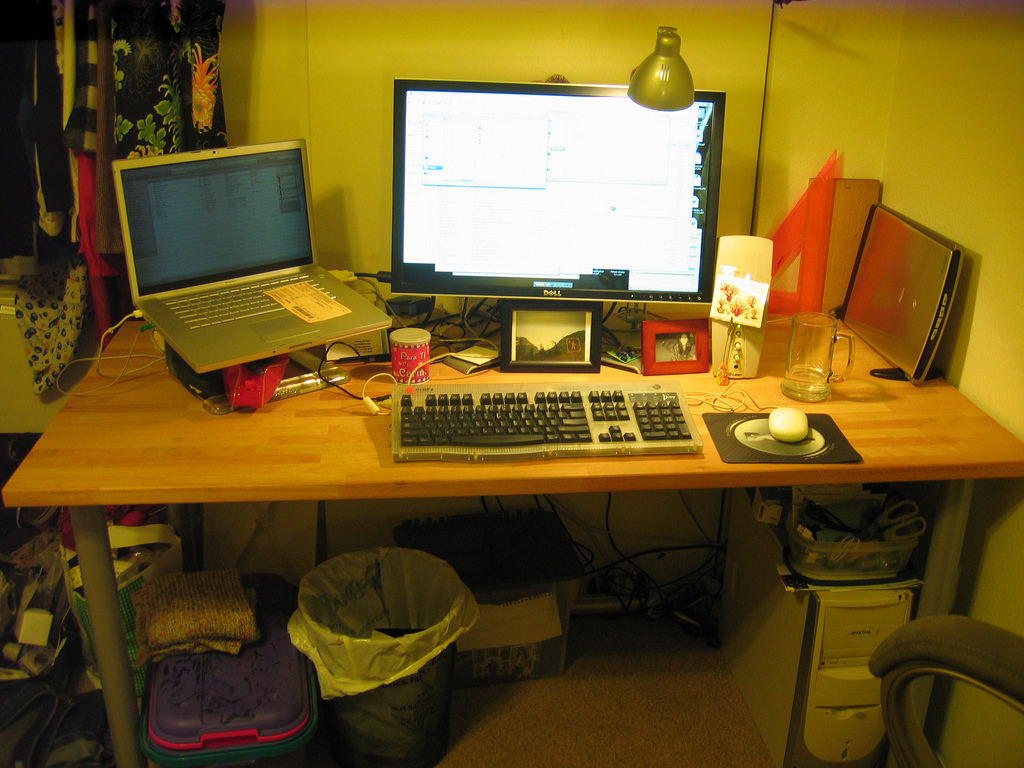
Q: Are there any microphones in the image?
A: No, there are no microphones.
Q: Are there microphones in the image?
A: No, there are no microphones.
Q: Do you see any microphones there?
A: No, there are no microphones.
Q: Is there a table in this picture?
A: Yes, there is a table.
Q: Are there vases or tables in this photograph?
A: Yes, there is a table.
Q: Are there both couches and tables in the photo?
A: No, there is a table but no couches.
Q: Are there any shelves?
A: No, there are no shelves.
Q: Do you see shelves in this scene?
A: No, there are no shelves.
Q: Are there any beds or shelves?
A: No, there are no shelves or beds.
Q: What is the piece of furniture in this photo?
A: The piece of furniture is a table.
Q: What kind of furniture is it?
A: The piece of furniture is a table.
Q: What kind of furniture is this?
A: This is a table.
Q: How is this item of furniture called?
A: This is a table.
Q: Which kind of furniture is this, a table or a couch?
A: This is a table.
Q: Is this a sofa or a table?
A: This is a table.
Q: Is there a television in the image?
A: No, there are no televisions.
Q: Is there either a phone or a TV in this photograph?
A: No, there are no televisions or phones.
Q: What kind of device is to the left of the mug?
A: The devices are computers.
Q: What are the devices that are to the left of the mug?
A: The devices are computers.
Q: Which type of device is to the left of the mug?
A: The devices are computers.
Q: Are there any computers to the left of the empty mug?
A: Yes, there are computers to the left of the mug.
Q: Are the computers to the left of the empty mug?
A: Yes, the computers are to the left of the mug.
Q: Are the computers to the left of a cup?
A: No, the computers are to the left of the mug.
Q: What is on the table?
A: The computers are on the table.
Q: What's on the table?
A: The computers are on the table.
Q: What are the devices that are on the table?
A: The devices are computers.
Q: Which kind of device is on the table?
A: The devices are computers.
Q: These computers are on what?
A: The computers are on the table.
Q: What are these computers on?
A: The computers are on the table.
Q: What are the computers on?
A: The computers are on the table.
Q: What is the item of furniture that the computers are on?
A: The piece of furniture is a table.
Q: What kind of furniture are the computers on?
A: The computers are on the table.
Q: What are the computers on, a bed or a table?
A: The computers are on a table.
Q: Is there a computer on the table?
A: Yes, there are computers on the table.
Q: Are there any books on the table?
A: No, there are computers on the table.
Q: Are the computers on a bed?
A: No, the computers are on the table.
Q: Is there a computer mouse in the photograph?
A: Yes, there is a computer mouse.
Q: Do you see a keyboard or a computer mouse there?
A: Yes, there is a computer mouse.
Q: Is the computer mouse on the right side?
A: Yes, the computer mouse is on the right of the image.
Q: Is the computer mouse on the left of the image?
A: No, the computer mouse is on the right of the image.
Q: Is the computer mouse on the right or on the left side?
A: The computer mouse is on the right of the image.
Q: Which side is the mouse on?
A: The mouse is on the right of the image.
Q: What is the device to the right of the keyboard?
A: The device is a computer mouse.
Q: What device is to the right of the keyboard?
A: The device is a computer mouse.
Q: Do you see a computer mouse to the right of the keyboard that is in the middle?
A: Yes, there is a computer mouse to the right of the keyboard.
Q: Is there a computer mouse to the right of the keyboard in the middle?
A: Yes, there is a computer mouse to the right of the keyboard.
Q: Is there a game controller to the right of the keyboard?
A: No, there is a computer mouse to the right of the keyboard.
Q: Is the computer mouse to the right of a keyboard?
A: Yes, the computer mouse is to the right of a keyboard.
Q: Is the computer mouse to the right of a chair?
A: No, the computer mouse is to the right of a keyboard.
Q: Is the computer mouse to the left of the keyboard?
A: No, the computer mouse is to the right of the keyboard.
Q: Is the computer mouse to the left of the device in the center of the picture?
A: No, the computer mouse is to the right of the keyboard.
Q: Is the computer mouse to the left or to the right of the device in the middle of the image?
A: The computer mouse is to the right of the keyboard.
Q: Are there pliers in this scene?
A: No, there are no pliers.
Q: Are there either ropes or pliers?
A: No, there are no pliers or ropes.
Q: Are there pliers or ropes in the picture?
A: No, there are no pliers or ropes.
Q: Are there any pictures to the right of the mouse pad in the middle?
A: Yes, there is a picture to the right of the mousepad.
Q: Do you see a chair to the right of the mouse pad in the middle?
A: No, there is a picture to the right of the mouse pad.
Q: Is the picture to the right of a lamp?
A: No, the picture is to the right of a mouse pad.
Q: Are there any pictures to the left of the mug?
A: Yes, there is a picture to the left of the mug.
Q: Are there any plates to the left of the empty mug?
A: No, there is a picture to the left of the mug.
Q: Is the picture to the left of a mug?
A: Yes, the picture is to the left of a mug.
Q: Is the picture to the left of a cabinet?
A: No, the picture is to the left of a mug.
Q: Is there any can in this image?
A: Yes, there is a can.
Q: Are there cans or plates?
A: Yes, there is a can.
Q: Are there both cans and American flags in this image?
A: No, there is a can but no American flags.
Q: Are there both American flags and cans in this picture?
A: No, there is a can but no American flags.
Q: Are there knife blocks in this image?
A: No, there are no knife blocks.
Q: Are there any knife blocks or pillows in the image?
A: No, there are no knife blocks or pillows.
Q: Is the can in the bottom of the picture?
A: Yes, the can is in the bottom of the image.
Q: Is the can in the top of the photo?
A: No, the can is in the bottom of the image.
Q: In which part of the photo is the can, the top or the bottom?
A: The can is in the bottom of the image.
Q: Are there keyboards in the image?
A: Yes, there is a keyboard.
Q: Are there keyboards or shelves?
A: Yes, there is a keyboard.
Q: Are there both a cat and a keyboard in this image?
A: No, there is a keyboard but no cats.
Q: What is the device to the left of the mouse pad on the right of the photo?
A: The device is a keyboard.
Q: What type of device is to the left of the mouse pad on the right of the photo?
A: The device is a keyboard.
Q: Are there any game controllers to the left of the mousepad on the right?
A: No, there is a keyboard to the left of the mousepad.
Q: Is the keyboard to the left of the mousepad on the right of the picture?
A: Yes, the keyboard is to the left of the mouse pad.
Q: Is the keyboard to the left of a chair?
A: No, the keyboard is to the left of the mouse pad.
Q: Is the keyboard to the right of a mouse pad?
A: No, the keyboard is to the left of a mouse pad.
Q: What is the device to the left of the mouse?
A: The device is a keyboard.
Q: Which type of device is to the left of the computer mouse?
A: The device is a keyboard.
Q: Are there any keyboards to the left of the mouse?
A: Yes, there is a keyboard to the left of the mouse.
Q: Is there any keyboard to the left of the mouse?
A: Yes, there is a keyboard to the left of the mouse.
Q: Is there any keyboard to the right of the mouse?
A: No, the keyboard is to the left of the mouse.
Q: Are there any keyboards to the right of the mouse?
A: No, the keyboard is to the left of the mouse.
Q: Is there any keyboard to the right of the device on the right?
A: No, the keyboard is to the left of the mouse.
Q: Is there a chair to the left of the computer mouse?
A: No, there is a keyboard to the left of the computer mouse.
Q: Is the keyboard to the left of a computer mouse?
A: Yes, the keyboard is to the left of a computer mouse.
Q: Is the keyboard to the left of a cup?
A: No, the keyboard is to the left of a computer mouse.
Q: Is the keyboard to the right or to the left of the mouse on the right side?
A: The keyboard is to the left of the computer mouse.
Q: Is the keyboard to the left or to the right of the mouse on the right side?
A: The keyboard is to the left of the computer mouse.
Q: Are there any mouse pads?
A: Yes, there is a mouse pad.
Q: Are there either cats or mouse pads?
A: Yes, there is a mouse pad.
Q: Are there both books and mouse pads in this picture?
A: No, there is a mouse pad but no books.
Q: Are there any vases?
A: No, there are no vases.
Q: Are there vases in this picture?
A: No, there are no vases.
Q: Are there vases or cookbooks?
A: No, there are no vases or cookbooks.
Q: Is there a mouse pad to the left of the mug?
A: Yes, there is a mouse pad to the left of the mug.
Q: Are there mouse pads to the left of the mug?
A: Yes, there is a mouse pad to the left of the mug.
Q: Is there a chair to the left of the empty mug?
A: No, there is a mouse pad to the left of the mug.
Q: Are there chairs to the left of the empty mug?
A: No, there is a mouse pad to the left of the mug.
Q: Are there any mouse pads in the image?
A: Yes, there is a mouse pad.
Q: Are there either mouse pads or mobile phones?
A: Yes, there is a mouse pad.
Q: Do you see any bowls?
A: No, there are no bowls.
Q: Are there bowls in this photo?
A: No, there are no bowls.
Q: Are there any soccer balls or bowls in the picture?
A: No, there are no bowls or soccer balls.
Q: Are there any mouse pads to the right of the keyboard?
A: Yes, there is a mouse pad to the right of the keyboard.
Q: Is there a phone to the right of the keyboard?
A: No, there is a mouse pad to the right of the keyboard.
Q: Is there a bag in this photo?
A: Yes, there is a bag.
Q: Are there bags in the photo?
A: Yes, there is a bag.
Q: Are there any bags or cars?
A: Yes, there is a bag.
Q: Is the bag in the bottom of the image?
A: Yes, the bag is in the bottom of the image.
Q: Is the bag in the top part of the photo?
A: No, the bag is in the bottom of the image.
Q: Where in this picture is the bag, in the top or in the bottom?
A: The bag is in the bottom of the image.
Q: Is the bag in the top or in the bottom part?
A: The bag is in the bottom of the image.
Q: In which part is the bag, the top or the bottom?
A: The bag is in the bottom of the image.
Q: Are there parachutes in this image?
A: No, there are no parachutes.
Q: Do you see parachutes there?
A: No, there are no parachutes.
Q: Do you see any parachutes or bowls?
A: No, there are no parachutes or bowls.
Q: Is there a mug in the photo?
A: Yes, there is a mug.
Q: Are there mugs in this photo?
A: Yes, there is a mug.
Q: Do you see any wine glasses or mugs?
A: Yes, there is a mug.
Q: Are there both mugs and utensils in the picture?
A: No, there is a mug but no utensils.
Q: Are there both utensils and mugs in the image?
A: No, there is a mug but no utensils.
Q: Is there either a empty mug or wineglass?
A: Yes, there is an empty mug.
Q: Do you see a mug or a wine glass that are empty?
A: Yes, the mug is empty.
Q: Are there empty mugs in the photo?
A: Yes, there is an empty mug.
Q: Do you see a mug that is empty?
A: Yes, there is a mug that is empty.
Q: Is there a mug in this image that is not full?
A: Yes, there is a empty mug.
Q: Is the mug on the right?
A: Yes, the mug is on the right of the image.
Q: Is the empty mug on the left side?
A: No, the mug is on the right of the image.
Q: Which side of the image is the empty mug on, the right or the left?
A: The mug is on the right of the image.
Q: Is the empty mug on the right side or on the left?
A: The mug is on the right of the image.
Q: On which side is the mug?
A: The mug is on the right of the image.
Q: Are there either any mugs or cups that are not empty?
A: No, there is a mug but it is empty.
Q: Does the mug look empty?
A: Yes, the mug is empty.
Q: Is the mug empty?
A: Yes, the mug is empty.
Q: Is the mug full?
A: No, the mug is empty.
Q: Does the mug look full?
A: No, the mug is empty.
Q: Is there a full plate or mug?
A: No, there is a mug but it is empty.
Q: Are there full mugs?
A: No, there is a mug but it is empty.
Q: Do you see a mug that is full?
A: No, there is a mug but it is empty.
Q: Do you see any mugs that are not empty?
A: No, there is a mug but it is empty.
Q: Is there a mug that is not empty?
A: No, there is a mug but it is empty.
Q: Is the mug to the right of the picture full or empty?
A: The mug is empty.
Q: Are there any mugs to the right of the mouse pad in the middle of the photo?
A: Yes, there is a mug to the right of the mouse pad.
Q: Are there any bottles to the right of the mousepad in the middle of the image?
A: No, there is a mug to the right of the mousepad.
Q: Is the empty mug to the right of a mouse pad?
A: Yes, the mug is to the right of a mouse pad.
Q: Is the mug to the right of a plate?
A: No, the mug is to the right of a mouse pad.